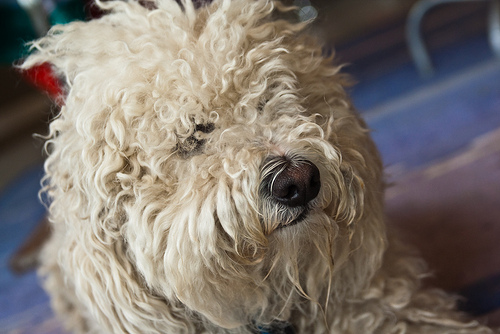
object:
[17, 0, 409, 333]
dog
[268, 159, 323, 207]
nose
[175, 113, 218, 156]
eye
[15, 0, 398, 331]
head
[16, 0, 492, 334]
fur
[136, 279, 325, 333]
collar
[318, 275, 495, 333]
leg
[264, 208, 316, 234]
mouth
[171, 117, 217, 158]
eyes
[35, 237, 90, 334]
tail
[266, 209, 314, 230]
lips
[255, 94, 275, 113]
eye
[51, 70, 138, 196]
ear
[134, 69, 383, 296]
face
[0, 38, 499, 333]
carpet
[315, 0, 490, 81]
table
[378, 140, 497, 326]
rug